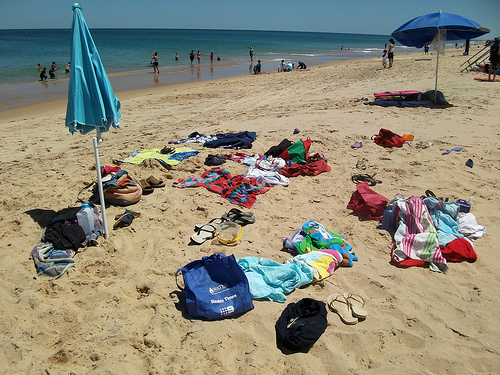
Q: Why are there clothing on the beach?
A: People changed clothes.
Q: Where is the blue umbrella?
A: Stuck in the sand.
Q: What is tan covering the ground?
A: Sand.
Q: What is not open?
A: Umbrella.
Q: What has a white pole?
A: Umbrella.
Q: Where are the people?
A: In the water.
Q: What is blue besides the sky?
A: Water.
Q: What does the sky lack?
A: Clouds.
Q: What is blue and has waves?
A: Water.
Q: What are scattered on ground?
A: Clothes.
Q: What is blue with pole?
A: Umbrella.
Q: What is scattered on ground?
A: Clothes.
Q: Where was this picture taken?
A: The beach.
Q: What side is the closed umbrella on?
A: Left.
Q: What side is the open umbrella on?
A: Right.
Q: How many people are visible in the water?
A: Eleven.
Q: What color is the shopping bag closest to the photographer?
A: Blue.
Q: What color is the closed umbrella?
A: Light blue.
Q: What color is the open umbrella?
A: Dark blue.